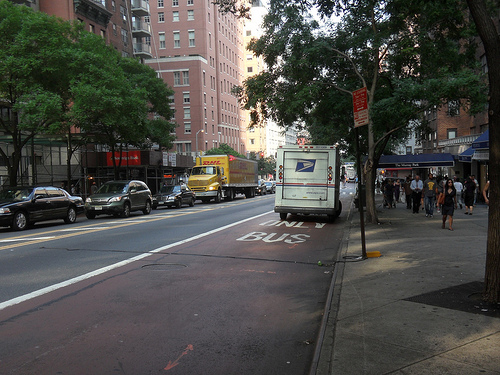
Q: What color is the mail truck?
A: White.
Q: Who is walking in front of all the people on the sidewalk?
A: A female.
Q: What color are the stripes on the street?
A: White.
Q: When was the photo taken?
A: Daytime.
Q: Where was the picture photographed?
A: Downtown.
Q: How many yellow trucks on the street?
A: One.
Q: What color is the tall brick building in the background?
A: Red.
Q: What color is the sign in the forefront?
A: Red and white.